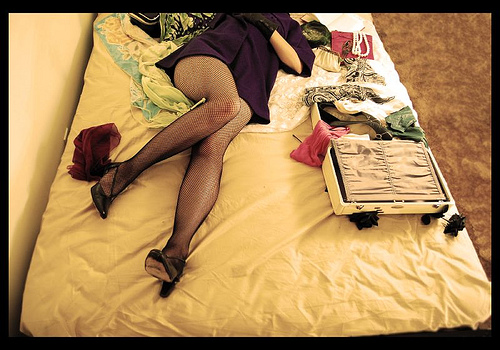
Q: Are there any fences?
A: No, there are no fences.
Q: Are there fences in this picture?
A: No, there are no fences.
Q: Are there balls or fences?
A: No, there are no fences or balls.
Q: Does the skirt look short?
A: Yes, the skirt is short.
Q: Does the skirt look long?
A: No, the skirt is short.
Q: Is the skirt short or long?
A: The skirt is short.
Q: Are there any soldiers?
A: No, there are no soldiers.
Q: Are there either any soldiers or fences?
A: No, there are no soldiers or fences.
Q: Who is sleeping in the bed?
A: The girl is sleeping in the bed.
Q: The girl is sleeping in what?
A: The girl is sleeping in the bed.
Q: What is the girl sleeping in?
A: The girl is sleeping in the bed.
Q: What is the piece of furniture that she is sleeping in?
A: The piece of furniture is a bed.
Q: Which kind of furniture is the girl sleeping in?
A: The girl is sleeping in the bed.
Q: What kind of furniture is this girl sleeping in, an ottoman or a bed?
A: The girl is sleeping in a bed.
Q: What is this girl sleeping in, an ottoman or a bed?
A: The girl is sleeping in a bed.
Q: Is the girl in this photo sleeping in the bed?
A: Yes, the girl is sleeping in the bed.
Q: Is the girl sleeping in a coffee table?
A: No, the girl is sleeping in the bed.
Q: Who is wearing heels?
A: The girl is wearing heels.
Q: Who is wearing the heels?
A: The girl is wearing heels.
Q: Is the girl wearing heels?
A: Yes, the girl is wearing heels.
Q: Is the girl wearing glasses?
A: No, the girl is wearing heels.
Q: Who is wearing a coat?
A: The girl is wearing a coat.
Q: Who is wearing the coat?
A: The girl is wearing a coat.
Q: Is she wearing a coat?
A: Yes, the girl is wearing a coat.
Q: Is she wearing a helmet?
A: No, the girl is wearing a coat.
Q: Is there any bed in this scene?
A: Yes, there is a bed.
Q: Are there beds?
A: Yes, there is a bed.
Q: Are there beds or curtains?
A: Yes, there is a bed.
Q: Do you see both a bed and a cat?
A: No, there is a bed but no cats.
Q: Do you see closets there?
A: No, there are no closets.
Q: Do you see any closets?
A: No, there are no closets.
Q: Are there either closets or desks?
A: No, there are no closets or desks.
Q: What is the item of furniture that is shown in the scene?
A: The piece of furniture is a bed.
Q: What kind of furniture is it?
A: The piece of furniture is a bed.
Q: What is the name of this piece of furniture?
A: This is a bed.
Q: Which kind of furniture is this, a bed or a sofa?
A: This is a bed.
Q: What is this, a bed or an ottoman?
A: This is a bed.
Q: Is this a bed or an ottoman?
A: This is a bed.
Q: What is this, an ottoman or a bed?
A: This is a bed.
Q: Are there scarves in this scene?
A: Yes, there is a scarf.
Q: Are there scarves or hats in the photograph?
A: Yes, there is a scarf.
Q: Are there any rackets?
A: No, there are no rackets.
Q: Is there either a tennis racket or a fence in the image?
A: No, there are no rackets or fences.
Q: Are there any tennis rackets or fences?
A: No, there are no tennis rackets or fences.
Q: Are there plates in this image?
A: No, there are no plates.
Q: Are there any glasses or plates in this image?
A: No, there are no plates or glasses.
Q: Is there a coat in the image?
A: Yes, there is a coat.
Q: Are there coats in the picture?
A: Yes, there is a coat.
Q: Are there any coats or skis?
A: Yes, there is a coat.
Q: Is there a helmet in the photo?
A: No, there are no helmets.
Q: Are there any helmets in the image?
A: No, there are no helmets.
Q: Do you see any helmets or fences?
A: No, there are no helmets or fences.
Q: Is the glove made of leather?
A: Yes, the glove is made of leather.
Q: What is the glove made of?
A: The glove is made of leather.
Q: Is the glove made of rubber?
A: No, the glove is made of leather.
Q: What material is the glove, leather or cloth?
A: The glove is made of leather.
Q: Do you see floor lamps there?
A: No, there are no floor lamps.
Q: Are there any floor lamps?
A: No, there are no floor lamps.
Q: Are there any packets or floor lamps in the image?
A: No, there are no floor lamps or packets.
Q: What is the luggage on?
A: The luggage is on the bed.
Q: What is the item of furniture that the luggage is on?
A: The piece of furniture is a bed.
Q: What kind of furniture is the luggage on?
A: The luggage is on the bed.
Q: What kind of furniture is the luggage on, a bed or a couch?
A: The luggage is on a bed.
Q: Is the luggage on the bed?
A: Yes, the luggage is on the bed.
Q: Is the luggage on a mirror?
A: No, the luggage is on the bed.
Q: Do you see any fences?
A: No, there are no fences.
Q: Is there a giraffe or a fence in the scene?
A: No, there are no fences or giraffes.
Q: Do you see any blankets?
A: Yes, there is a blanket.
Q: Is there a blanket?
A: Yes, there is a blanket.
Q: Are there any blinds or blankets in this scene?
A: Yes, there is a blanket.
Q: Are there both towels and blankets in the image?
A: No, there is a blanket but no towels.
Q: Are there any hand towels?
A: No, there are no hand towels.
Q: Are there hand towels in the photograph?
A: No, there are no hand towels.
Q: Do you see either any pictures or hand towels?
A: No, there are no hand towels or pictures.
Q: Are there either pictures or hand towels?
A: No, there are no hand towels or pictures.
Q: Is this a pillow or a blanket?
A: This is a blanket.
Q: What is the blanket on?
A: The blanket is on the bed.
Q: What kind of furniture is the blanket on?
A: The blanket is on the bed.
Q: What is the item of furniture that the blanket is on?
A: The piece of furniture is a bed.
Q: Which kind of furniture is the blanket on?
A: The blanket is on the bed.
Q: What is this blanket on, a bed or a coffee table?
A: The blanket is on a bed.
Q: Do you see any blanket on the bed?
A: Yes, there is a blanket on the bed.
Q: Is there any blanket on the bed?
A: Yes, there is a blanket on the bed.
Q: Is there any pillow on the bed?
A: No, there is a blanket on the bed.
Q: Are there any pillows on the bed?
A: No, there is a blanket on the bed.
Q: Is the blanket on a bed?
A: Yes, the blanket is on a bed.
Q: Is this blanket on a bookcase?
A: No, the blanket is on a bed.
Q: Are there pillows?
A: No, there are no pillows.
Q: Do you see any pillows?
A: No, there are no pillows.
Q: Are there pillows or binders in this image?
A: No, there are no pillows or binders.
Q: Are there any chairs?
A: No, there are no chairs.